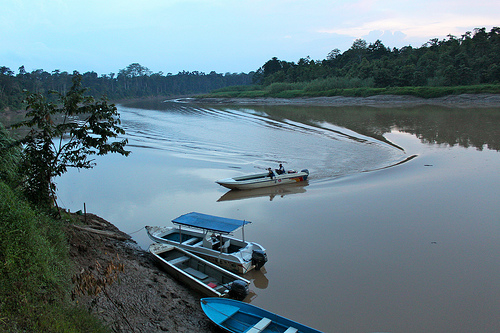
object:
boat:
[215, 170, 310, 189]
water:
[96, 99, 499, 197]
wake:
[107, 103, 401, 158]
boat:
[145, 225, 269, 274]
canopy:
[170, 211, 252, 234]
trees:
[15, 71, 130, 202]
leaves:
[361, 38, 499, 87]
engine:
[301, 169, 310, 181]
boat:
[149, 243, 251, 297]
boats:
[199, 296, 323, 333]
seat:
[276, 172, 286, 176]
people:
[266, 167, 275, 177]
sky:
[0, 1, 495, 70]